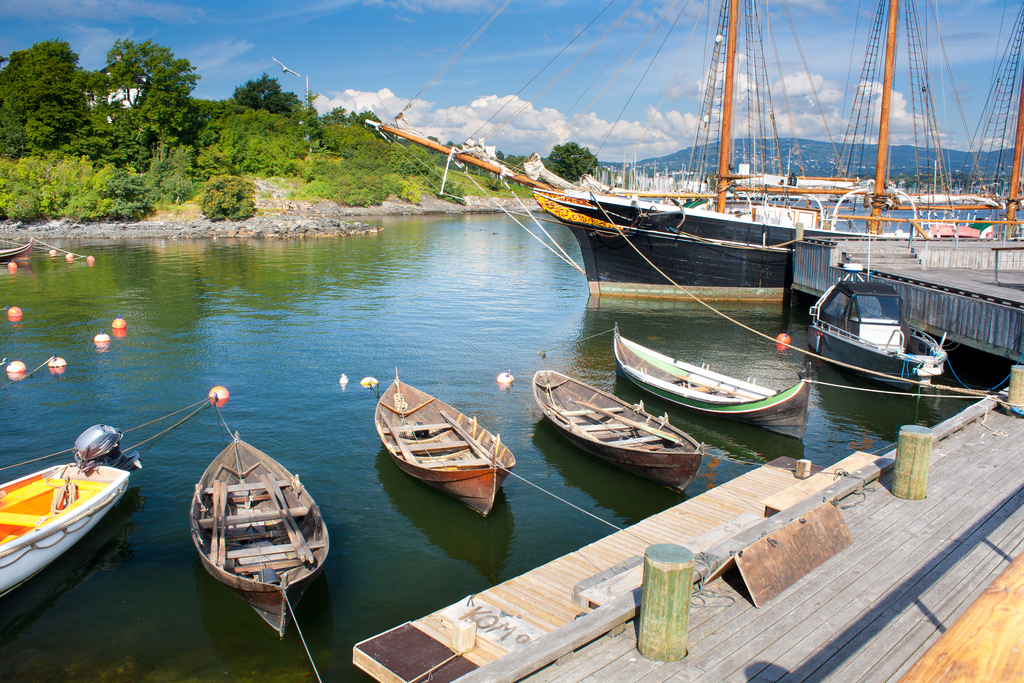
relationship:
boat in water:
[588, 186, 730, 283] [270, 246, 413, 319]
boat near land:
[588, 186, 730, 283] [186, 92, 318, 159]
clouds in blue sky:
[442, 83, 542, 137] [0, 0, 1023, 136]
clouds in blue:
[442, 83, 542, 137] [364, 25, 419, 53]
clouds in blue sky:
[443, 83, 542, 137] [365, 17, 458, 66]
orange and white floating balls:
[762, 334, 803, 362] [763, 322, 805, 353]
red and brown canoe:
[455, 455, 505, 502] [362, 391, 495, 525]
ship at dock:
[588, 186, 730, 283] [599, 169, 1000, 351]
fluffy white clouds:
[445, 99, 545, 148] [442, 83, 542, 137]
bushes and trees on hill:
[147, 101, 293, 184] [164, 116, 398, 225]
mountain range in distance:
[147, 101, 293, 184] [747, 116, 831, 178]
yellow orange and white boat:
[498, 170, 624, 239] [58, 413, 138, 522]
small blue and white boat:
[783, 285, 907, 382] [588, 186, 730, 283]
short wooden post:
[848, 212, 961, 273] [867, 156, 957, 265]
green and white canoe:
[616, 343, 758, 441] [665, 366, 839, 474]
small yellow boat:
[783, 285, 907, 382] [588, 186, 730, 283]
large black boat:
[628, 202, 746, 277] [588, 186, 730, 283]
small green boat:
[783, 285, 907, 382] [588, 186, 730, 283]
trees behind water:
[86, 59, 213, 136] [270, 246, 413, 319]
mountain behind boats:
[653, 127, 947, 188] [616, 160, 822, 288]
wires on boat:
[642, 158, 787, 251] [588, 186, 730, 283]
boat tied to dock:
[588, 186, 730, 283] [599, 169, 1000, 351]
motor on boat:
[833, 338, 970, 371] [588, 186, 730, 283]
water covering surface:
[270, 246, 413, 319] [280, 207, 515, 329]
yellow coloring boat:
[498, 170, 624, 239] [588, 186, 730, 283]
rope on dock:
[603, 199, 760, 325] [599, 169, 1000, 351]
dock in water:
[599, 169, 1000, 351] [270, 246, 413, 319]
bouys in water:
[445, 359, 539, 408] [270, 246, 413, 319]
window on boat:
[837, 278, 897, 315] [588, 186, 730, 283]